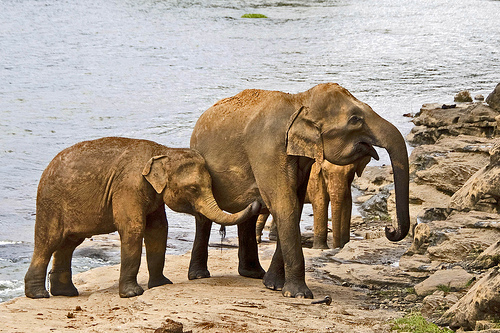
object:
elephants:
[25, 136, 263, 298]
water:
[0, 0, 500, 303]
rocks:
[183, 82, 500, 291]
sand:
[0, 241, 427, 332]